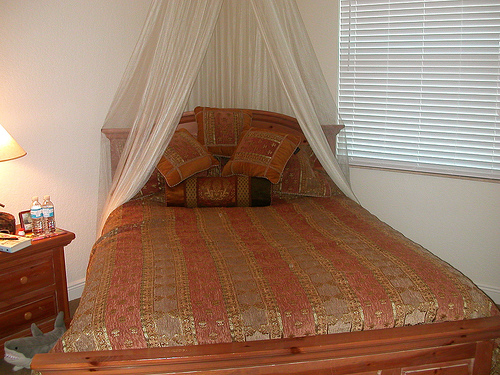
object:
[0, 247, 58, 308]
drawers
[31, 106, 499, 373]
bed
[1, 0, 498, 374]
bedroom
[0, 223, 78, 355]
night stand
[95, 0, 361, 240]
mosquito net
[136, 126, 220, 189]
pillows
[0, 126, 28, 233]
lamp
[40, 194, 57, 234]
water bottles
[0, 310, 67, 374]
whale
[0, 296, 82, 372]
floor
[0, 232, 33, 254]
book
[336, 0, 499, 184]
blinds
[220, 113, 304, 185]
pillows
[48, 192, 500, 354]
comforter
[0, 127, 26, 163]
shade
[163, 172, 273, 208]
pillow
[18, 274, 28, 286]
knob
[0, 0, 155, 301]
wall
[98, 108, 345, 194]
frame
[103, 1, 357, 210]
corner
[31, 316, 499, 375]
foot board